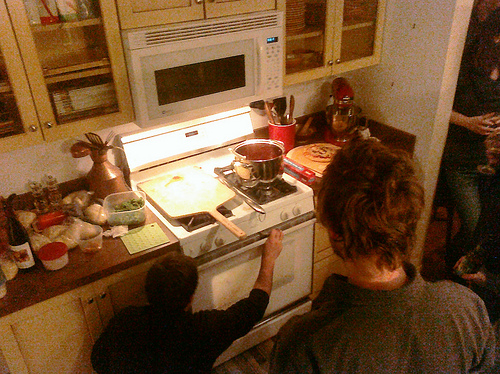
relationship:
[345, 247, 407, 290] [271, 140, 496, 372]
neck of a person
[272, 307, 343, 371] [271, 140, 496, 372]
shoulder of a person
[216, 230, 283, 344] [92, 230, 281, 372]
arm of a person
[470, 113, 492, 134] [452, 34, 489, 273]
hand of a person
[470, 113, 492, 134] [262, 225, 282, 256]
hand of a hand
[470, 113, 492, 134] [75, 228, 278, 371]
hand of a person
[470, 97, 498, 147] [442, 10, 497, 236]
fingers of a person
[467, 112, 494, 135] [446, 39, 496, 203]
hand of person